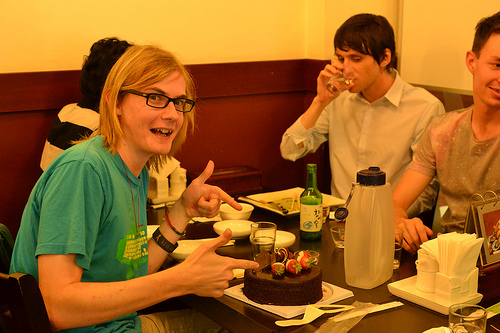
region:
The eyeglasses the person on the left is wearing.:
[132, 88, 194, 113]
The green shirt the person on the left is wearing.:
[23, 135, 147, 330]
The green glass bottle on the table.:
[299, 156, 324, 243]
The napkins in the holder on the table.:
[420, 229, 478, 297]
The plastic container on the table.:
[342, 156, 397, 286]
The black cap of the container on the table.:
[356, 162, 384, 187]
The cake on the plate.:
[239, 245, 323, 312]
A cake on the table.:
[239, 241, 334, 313]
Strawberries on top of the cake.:
[243, 235, 328, 317]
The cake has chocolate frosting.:
[238, 235, 335, 313]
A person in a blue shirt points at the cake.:
[16, 41, 327, 331]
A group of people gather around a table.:
[19, 5, 490, 325]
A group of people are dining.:
[37, 10, 497, 331]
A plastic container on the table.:
[337, 160, 402, 291]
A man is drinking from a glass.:
[262, 8, 444, 216]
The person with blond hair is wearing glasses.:
[7, 39, 272, 323]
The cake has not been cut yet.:
[230, 241, 355, 323]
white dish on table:
[221, 186, 255, 223]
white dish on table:
[214, 216, 255, 243]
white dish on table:
[247, 169, 347, 223]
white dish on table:
[251, 219, 291, 254]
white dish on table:
[165, 226, 233, 266]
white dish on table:
[141, 206, 175, 247]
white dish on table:
[412, 249, 440, 306]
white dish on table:
[434, 246, 479, 306]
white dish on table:
[374, 255, 462, 332]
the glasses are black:
[118, 78, 229, 145]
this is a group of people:
[44, 27, 464, 281]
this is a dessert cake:
[244, 234, 318, 276]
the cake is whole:
[238, 238, 319, 295]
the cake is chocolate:
[238, 223, 316, 287]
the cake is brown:
[258, 240, 309, 287]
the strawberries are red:
[264, 245, 356, 299]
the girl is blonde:
[72, 77, 196, 207]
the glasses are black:
[87, 78, 224, 155]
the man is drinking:
[284, 38, 396, 148]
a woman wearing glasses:
[120, 85, 205, 114]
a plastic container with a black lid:
[340, 164, 402, 289]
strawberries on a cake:
[272, 244, 320, 279]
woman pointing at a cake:
[14, 51, 258, 329]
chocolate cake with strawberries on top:
[242, 245, 331, 305]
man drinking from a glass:
[313, 8, 403, 106]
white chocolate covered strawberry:
[285, 257, 302, 274]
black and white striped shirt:
[45, 105, 98, 142]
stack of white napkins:
[427, 230, 483, 280]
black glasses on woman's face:
[122, 80, 196, 113]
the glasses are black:
[120, 87, 197, 112]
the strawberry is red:
[271, 260, 285, 277]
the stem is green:
[272, 265, 284, 275]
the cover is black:
[354, 165, 384, 187]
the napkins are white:
[419, 228, 483, 282]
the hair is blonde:
[70, 42, 195, 172]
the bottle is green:
[299, 163, 325, 245]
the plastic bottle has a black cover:
[335, 166, 397, 288]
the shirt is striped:
[39, 98, 104, 173]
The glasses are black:
[118, 88, 194, 115]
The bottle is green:
[297, 163, 324, 243]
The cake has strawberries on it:
[241, 248, 324, 305]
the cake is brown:
[242, 250, 324, 304]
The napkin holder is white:
[434, 265, 481, 300]